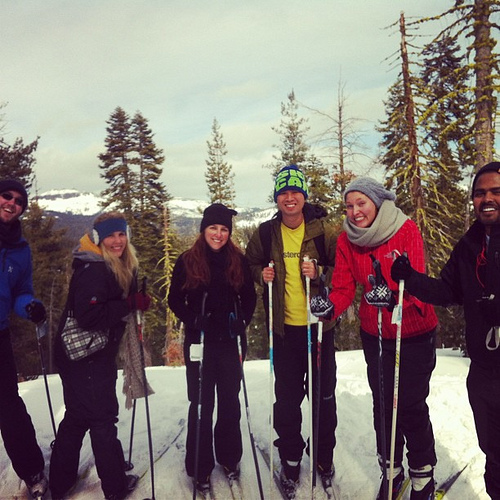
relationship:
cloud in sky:
[163, 140, 209, 174] [2, 3, 498, 208]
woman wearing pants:
[182, 337, 245, 477] [185, 327, 255, 489]